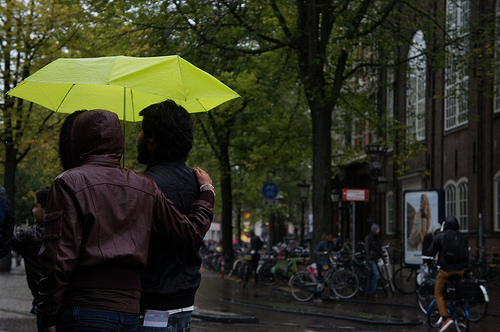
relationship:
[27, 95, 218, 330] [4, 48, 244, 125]
two people under yellow umbrella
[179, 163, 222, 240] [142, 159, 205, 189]
arm over shoulder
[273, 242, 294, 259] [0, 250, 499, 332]
bicycle parked on road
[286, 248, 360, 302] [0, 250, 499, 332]
bicycle parked on road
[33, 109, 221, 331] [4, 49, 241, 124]
people holding umbrella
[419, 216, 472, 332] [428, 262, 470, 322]
person wearing brown pants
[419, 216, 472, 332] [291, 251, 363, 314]
person riding bike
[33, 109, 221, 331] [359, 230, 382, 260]
people wearing coat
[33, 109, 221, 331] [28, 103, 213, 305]
people wearing leather jacket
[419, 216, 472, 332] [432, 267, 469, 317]
person wearing brown pants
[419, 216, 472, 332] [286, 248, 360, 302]
person sitting on bicycle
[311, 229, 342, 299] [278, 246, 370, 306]
person carrying bike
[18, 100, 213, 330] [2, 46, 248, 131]
people under umbrella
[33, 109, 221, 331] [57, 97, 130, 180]
people wearing hood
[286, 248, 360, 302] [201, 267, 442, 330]
bicycle on street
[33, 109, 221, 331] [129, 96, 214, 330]
people has man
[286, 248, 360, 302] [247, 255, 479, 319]
bicycle by curb